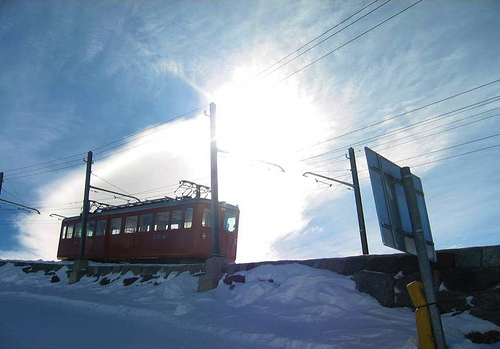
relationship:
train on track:
[47, 184, 247, 264] [0, 246, 499, 346]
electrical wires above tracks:
[384, 86, 485, 191] [12, 8, 492, 183]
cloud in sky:
[149, 77, 208, 122] [0, 0, 492, 142]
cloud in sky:
[227, 5, 303, 43] [0, 0, 492, 142]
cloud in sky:
[370, 57, 452, 97] [0, 0, 492, 142]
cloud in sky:
[449, 176, 494, 219] [0, 0, 492, 142]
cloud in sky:
[22, 52, 88, 109] [0, 0, 492, 142]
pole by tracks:
[63, 148, 99, 284] [12, 248, 497, 280]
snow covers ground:
[3, 263, 498, 347] [2, 256, 494, 343]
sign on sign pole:
[365, 145, 447, 347] [396, 165, 448, 346]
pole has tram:
[346, 145, 370, 254] [58, 196, 238, 266]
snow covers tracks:
[89, 260, 179, 267] [87, 262, 194, 273]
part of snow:
[304, 295, 345, 328] [169, 288, 369, 345]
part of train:
[167, 220, 180, 250] [55, 195, 241, 263]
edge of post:
[415, 252, 426, 306] [396, 239, 458, 346]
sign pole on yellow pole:
[396, 165, 448, 346] [406, 280, 433, 346]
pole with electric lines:
[346, 145, 370, 254] [0, 0, 498, 224]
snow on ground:
[3, 263, 498, 347] [1, 305, 498, 347]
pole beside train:
[194, 74, 236, 210] [19, 197, 301, 267]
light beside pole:
[300, 170, 352, 192] [346, 145, 368, 257]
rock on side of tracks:
[352, 269, 394, 307] [1, 249, 498, 292]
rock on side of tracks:
[225, 275, 245, 287] [1, 249, 498, 292]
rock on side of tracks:
[121, 276, 137, 284] [1, 249, 498, 292]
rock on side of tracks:
[50, 274, 59, 281] [1, 249, 498, 292]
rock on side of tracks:
[97, 277, 111, 285] [1, 249, 498, 292]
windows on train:
[59, 202, 238, 240] [53, 194, 242, 261]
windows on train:
[55, 204, 239, 242] [53, 194, 242, 261]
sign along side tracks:
[365, 145, 447, 347] [6, 230, 498, 276]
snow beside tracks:
[3, 263, 498, 347] [1, 249, 498, 292]